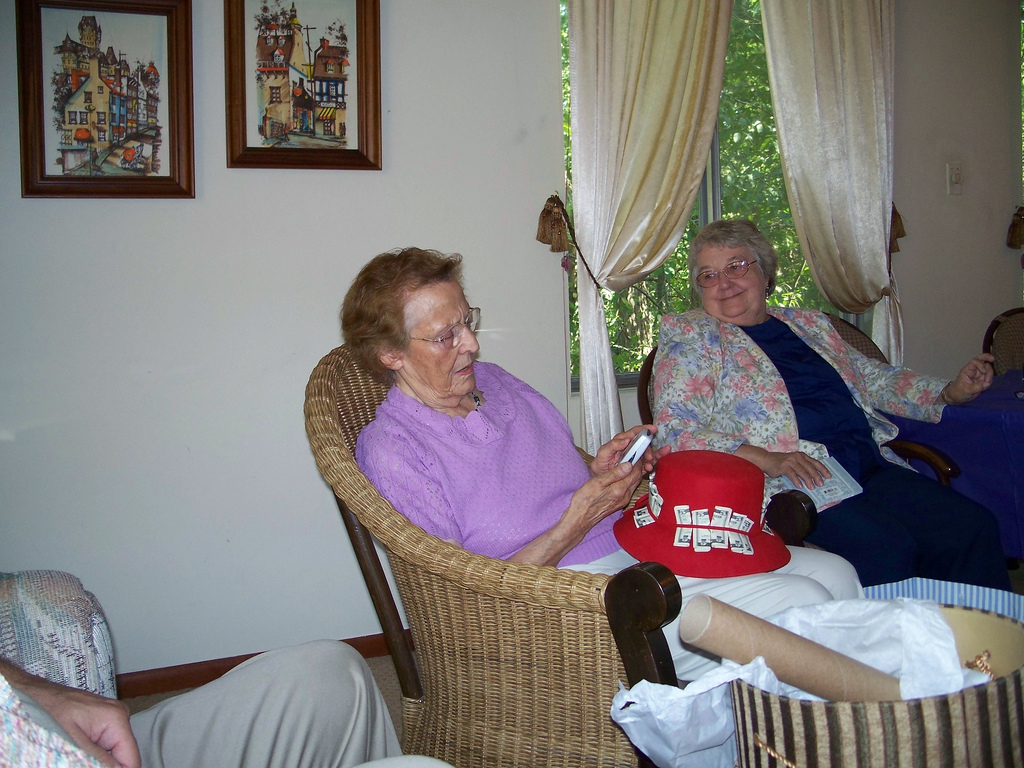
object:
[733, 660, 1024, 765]
bag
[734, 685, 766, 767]
stripe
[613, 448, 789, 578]
hat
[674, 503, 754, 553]
band